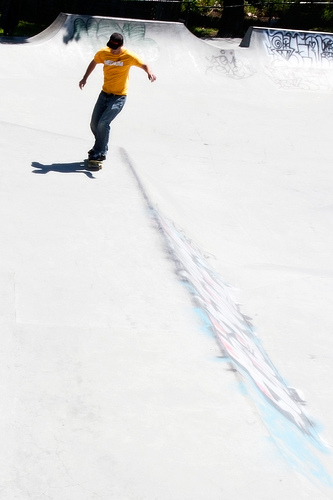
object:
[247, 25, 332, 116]
ramp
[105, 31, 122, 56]
head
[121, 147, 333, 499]
ramp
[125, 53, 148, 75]
left arm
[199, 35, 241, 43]
curb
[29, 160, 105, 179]
shadow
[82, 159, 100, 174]
skateboard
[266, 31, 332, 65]
design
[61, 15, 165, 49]
graffiti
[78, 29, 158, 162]
he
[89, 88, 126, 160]
blue jeans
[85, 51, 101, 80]
arm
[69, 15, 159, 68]
green design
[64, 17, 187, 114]
left wall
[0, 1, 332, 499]
photo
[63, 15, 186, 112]
ramp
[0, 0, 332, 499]
skate park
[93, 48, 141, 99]
shirt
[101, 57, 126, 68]
logo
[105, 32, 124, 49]
hat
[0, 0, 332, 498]
surface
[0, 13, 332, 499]
skatepark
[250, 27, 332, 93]
wall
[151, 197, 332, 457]
markings